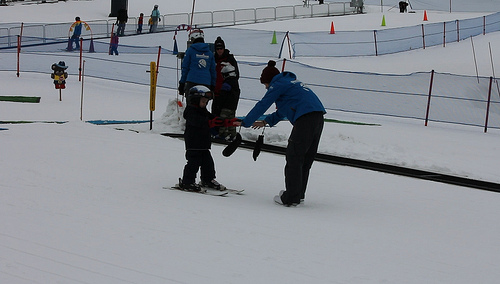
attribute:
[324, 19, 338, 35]
cone — orange, red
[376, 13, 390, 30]
cone — green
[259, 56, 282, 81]
hat — black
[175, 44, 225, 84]
jacket — blue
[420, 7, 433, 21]
cone — orange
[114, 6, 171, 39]
people — walking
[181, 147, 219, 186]
pants — black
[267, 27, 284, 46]
cone — green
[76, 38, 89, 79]
posts — red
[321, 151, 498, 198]
railing — black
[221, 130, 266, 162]
gloves — black